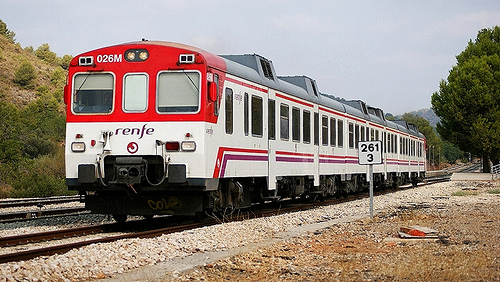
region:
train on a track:
[61, 36, 431, 225]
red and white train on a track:
[62, 36, 428, 226]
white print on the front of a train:
[95, 51, 124, 63]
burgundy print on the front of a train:
[110, 122, 157, 139]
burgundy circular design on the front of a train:
[122, 138, 139, 153]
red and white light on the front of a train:
[163, 138, 198, 153]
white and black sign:
[356, 137, 386, 219]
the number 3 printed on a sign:
[364, 150, 376, 164]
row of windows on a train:
[221, 86, 431, 158]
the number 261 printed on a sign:
[360, 143, 381, 153]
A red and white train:
[64, 37, 427, 233]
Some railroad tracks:
[0, 158, 482, 261]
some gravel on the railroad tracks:
[1, 158, 482, 278]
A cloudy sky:
[0, 1, 499, 112]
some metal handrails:
[486, 157, 498, 177]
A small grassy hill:
[1, 20, 72, 197]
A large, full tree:
[431, 25, 496, 172]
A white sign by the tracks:
[356, 140, 383, 165]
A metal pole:
[367, 163, 376, 220]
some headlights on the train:
[71, 140, 200, 154]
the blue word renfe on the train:
[114, 124, 155, 140]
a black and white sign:
[359, 140, 379, 160]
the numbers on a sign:
[361, 140, 378, 158]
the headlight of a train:
[69, 138, 84, 151]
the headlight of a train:
[180, 141, 192, 151]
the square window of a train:
[72, 73, 116, 115]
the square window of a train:
[155, 73, 197, 110]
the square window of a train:
[250, 92, 263, 140]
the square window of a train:
[223, 85, 233, 135]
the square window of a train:
[278, 101, 291, 138]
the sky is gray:
[170, 6, 413, 38]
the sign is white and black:
[351, 141, 384, 167]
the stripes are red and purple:
[228, 141, 360, 175]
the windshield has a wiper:
[73, 69, 96, 94]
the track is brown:
[29, 204, 81, 252]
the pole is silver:
[365, 175, 378, 222]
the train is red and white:
[55, 30, 470, 212]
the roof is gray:
[227, 52, 277, 76]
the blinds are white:
[155, 78, 199, 106]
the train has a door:
[261, 78, 286, 192]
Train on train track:
[63, 39, 428, 221]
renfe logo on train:
[110, 120, 156, 140]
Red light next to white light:
[162, 140, 179, 150]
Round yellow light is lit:
[122, 48, 137, 62]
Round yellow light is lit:
[138, 50, 148, 60]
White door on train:
[265, 87, 279, 190]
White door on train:
[311, 98, 321, 186]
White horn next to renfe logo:
[100, 129, 115, 153]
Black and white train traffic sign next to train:
[354, 137, 385, 213]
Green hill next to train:
[0, 15, 79, 196]